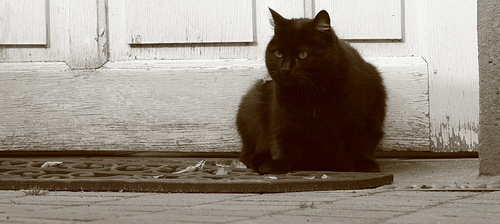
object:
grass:
[19, 185, 49, 196]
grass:
[300, 200, 315, 209]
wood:
[0, 60, 479, 146]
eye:
[295, 49, 311, 60]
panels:
[0, 0, 68, 62]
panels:
[108, 0, 275, 63]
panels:
[308, 0, 425, 57]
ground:
[0, 187, 500, 223]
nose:
[280, 62, 292, 74]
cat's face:
[264, 33, 342, 88]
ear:
[265, 6, 288, 28]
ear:
[312, 9, 331, 31]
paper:
[174, 160, 247, 176]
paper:
[41, 161, 63, 168]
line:
[425, 62, 430, 152]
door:
[0, 0, 485, 152]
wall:
[475, 0, 500, 175]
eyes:
[273, 49, 287, 58]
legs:
[255, 84, 304, 175]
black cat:
[235, 6, 390, 176]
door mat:
[0, 158, 395, 195]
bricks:
[0, 180, 500, 224]